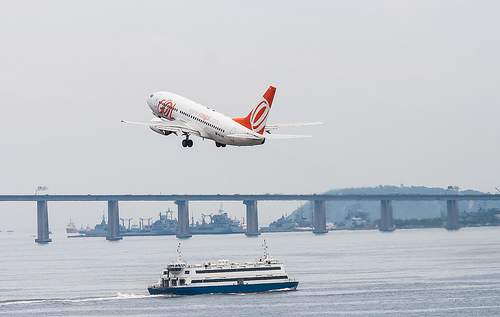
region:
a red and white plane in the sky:
[107, 50, 315, 176]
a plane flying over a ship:
[47, 36, 457, 311]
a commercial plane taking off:
[56, 40, 448, 315]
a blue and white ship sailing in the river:
[148, 243, 302, 298]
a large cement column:
[31, 204, 69, 250]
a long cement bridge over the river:
[7, 191, 494, 201]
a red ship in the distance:
[54, 215, 81, 234]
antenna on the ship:
[174, 243, 189, 262]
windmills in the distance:
[119, 213, 161, 230]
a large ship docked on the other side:
[206, 208, 241, 239]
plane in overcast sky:
[136, 85, 306, 172]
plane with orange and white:
[109, 76, 307, 161]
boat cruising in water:
[138, 236, 304, 306]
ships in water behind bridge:
[74, 186, 255, 242]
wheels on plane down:
[118, 94, 330, 162]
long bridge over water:
[96, 184, 476, 238]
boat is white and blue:
[127, 244, 369, 299]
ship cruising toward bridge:
[56, 186, 88, 246]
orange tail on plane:
[214, 73, 298, 153]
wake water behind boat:
[52, 270, 192, 310]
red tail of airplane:
[232, 84, 275, 136]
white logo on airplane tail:
[248, 97, 268, 134]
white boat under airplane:
[147, 236, 302, 294]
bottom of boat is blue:
[145, 281, 300, 295]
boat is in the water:
[1, 215, 499, 312]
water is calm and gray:
[1, 227, 499, 315]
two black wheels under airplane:
[181, 131, 194, 146]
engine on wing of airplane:
[149, 115, 171, 135]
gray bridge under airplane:
[0, 192, 499, 243]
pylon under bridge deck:
[175, 199, 194, 236]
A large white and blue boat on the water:
[142, 250, 304, 297]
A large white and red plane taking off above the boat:
[114, 77, 327, 159]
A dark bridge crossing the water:
[0, 190, 499, 245]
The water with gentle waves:
[0, 220, 499, 314]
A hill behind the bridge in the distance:
[253, 180, 498, 235]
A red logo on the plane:
[150, 96, 181, 121]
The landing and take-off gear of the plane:
[151, 127, 230, 154]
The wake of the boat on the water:
[0, 286, 177, 313]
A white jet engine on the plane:
[144, 114, 174, 137]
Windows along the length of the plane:
[156, 98, 227, 135]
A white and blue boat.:
[147, 237, 304, 314]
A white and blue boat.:
[155, 240, 253, 295]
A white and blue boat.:
[168, 250, 225, 275]